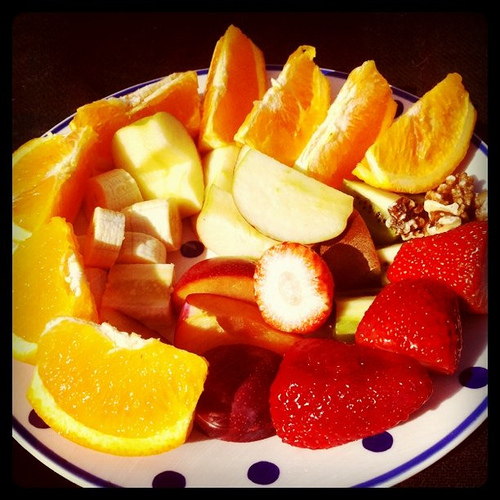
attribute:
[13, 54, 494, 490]
plate — white, blue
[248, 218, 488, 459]
strawberries — red, sliced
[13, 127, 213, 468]
oranges — orange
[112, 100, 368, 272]
apples — sliced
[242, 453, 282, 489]
dots — blue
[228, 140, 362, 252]
apple — white, green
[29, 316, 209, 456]
lemon wedge — small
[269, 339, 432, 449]
strawberry — sliced, half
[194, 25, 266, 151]
orange — wedge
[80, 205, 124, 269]
banana — slice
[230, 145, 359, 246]
apple — wedge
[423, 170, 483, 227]
walnut — brown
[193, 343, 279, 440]
skin — red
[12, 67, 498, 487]
ring — blue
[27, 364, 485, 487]
dots — blue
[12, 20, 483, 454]
food — snack, healthy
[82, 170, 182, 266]
bananas — Sliced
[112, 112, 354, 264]
apple — Cored, quartered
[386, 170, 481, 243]
walnuts — shelled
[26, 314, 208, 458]
orange — sliced